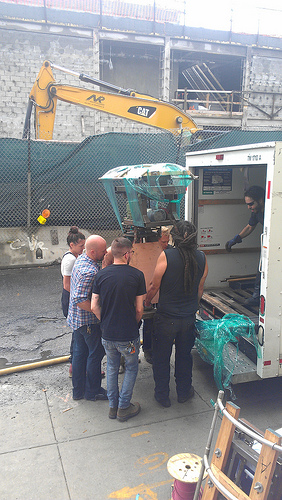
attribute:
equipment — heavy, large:
[51, 85, 229, 341]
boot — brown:
[74, 373, 175, 428]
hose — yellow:
[9, 351, 60, 401]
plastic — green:
[183, 296, 255, 403]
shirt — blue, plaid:
[64, 250, 116, 341]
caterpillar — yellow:
[26, 199, 52, 236]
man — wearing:
[223, 181, 271, 251]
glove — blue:
[219, 232, 251, 269]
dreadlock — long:
[117, 166, 198, 218]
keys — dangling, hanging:
[107, 324, 159, 375]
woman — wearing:
[35, 287, 87, 346]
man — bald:
[84, 212, 116, 262]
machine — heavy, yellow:
[0, 28, 233, 219]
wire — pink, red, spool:
[170, 453, 196, 497]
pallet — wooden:
[172, 386, 268, 495]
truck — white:
[153, 116, 281, 372]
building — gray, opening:
[15, 19, 275, 140]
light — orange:
[202, 137, 235, 171]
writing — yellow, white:
[132, 448, 173, 495]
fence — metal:
[4, 105, 167, 225]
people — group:
[30, 177, 255, 429]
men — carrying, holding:
[42, 176, 265, 315]